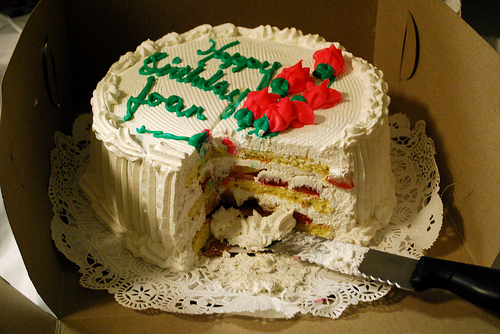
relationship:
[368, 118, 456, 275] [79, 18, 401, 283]
dolly underneath cake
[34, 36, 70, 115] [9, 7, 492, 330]
fold in cardboard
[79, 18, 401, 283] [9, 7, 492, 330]
cake inside cardboard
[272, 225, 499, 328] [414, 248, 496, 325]
knife has handle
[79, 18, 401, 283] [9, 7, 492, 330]
cake in cardboard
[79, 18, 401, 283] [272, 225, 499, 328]
cake with knife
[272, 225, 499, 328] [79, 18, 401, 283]
knife with cake